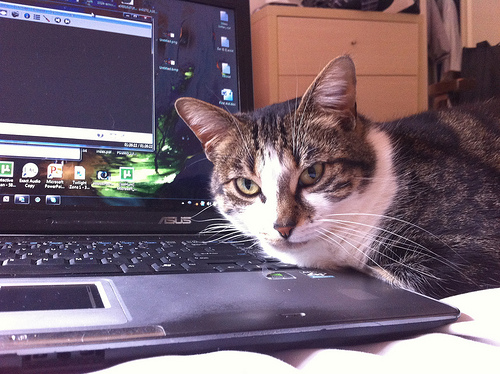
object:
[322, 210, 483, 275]
whisker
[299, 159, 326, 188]
eye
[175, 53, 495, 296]
cat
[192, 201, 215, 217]
whisker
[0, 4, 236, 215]
screen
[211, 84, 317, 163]
whiskers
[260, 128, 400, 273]
ruff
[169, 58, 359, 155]
ears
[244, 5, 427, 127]
cabinet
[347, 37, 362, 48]
knob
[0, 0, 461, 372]
laptop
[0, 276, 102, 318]
touchpad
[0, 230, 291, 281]
keyboard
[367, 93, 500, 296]
fur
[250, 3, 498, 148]
office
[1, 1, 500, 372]
photo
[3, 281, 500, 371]
desk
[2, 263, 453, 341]
panel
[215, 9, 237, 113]
icons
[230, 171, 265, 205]
eyes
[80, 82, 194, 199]
swirl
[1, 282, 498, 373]
blanket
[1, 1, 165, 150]
window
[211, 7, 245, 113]
row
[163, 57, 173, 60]
pair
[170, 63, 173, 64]
stickers